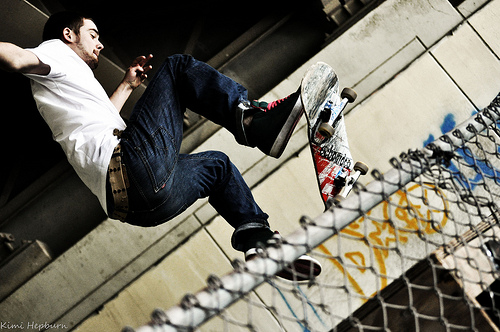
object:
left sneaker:
[231, 222, 321, 287]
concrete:
[1, 0, 499, 330]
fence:
[121, 96, 498, 331]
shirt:
[32, 37, 133, 217]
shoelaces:
[262, 98, 292, 112]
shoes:
[230, 216, 323, 284]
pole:
[143, 106, 486, 331]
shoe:
[241, 84, 309, 159]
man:
[2, 12, 371, 278]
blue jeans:
[110, 54, 254, 226]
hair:
[40, 13, 93, 44]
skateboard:
[292, 58, 369, 215]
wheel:
[333, 194, 348, 207]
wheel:
[351, 160, 371, 174]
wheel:
[340, 86, 357, 103]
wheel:
[317, 121, 335, 137]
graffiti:
[291, 101, 499, 293]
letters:
[317, 111, 497, 302]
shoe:
[228, 205, 397, 289]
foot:
[250, 82, 313, 159]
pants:
[107, 51, 269, 223]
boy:
[2, 13, 322, 281]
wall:
[4, 3, 498, 330]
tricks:
[1, 0, 389, 304]